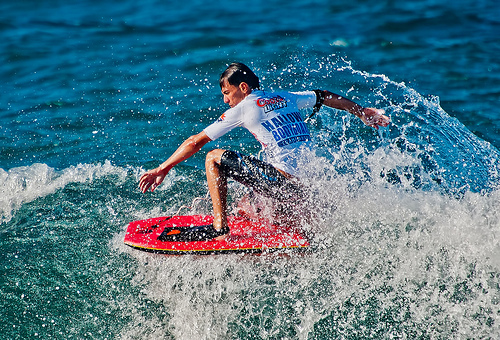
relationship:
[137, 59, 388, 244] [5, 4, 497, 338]
man in photo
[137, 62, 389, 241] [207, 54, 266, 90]
man has wet hair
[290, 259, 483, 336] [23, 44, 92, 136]
wave in water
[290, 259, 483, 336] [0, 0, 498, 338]
wave in water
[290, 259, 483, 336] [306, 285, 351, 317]
wave in water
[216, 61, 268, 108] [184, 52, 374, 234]
head of person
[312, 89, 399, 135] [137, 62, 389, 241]
arm of man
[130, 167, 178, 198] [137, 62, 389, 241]
hand of man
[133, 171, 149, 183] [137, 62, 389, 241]
finger of man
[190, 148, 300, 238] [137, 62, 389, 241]
leg of man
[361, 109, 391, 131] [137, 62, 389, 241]
hand of man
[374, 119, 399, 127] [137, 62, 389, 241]
finger of a man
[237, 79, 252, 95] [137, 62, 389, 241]
ear of a man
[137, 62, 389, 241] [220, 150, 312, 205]
man wearing shorts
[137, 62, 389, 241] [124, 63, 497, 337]
man crests wave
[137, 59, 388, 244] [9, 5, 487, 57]
man surfing in sea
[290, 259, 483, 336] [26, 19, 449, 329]
wave of sea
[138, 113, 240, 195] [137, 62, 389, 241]
arm of man